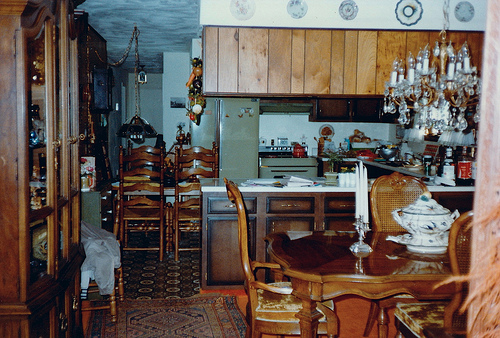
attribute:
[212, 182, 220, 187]
counter — white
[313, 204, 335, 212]
cabinets — brown, wood, wooden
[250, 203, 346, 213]
drawers — brown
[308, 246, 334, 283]
table — wooden, polished, wood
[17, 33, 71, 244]
cabinet — wooden, wood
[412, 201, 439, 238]
tureen — covered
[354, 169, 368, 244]
candles — white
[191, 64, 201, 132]
fruit — fake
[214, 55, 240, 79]
wall — blue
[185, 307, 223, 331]
rug — woven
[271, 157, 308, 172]
stove — green, cream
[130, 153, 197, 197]
chairs — wooden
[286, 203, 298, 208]
handles — gold